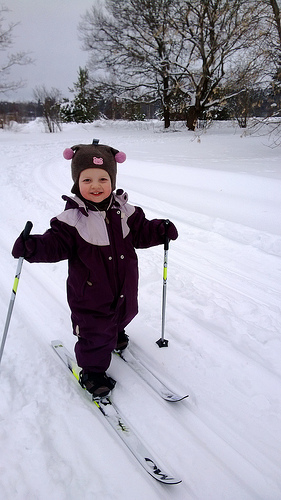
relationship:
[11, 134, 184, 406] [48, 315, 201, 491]
girl wearing skis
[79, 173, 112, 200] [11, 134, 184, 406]
face of girl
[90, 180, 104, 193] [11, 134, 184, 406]
nose of girl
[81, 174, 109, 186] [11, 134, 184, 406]
eyes of girl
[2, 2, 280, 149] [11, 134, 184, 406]
trees behind girl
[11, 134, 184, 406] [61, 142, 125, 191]
girl wearing cap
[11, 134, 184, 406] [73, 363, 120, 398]
girl wearing boot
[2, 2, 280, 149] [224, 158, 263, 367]
trees covered in snow